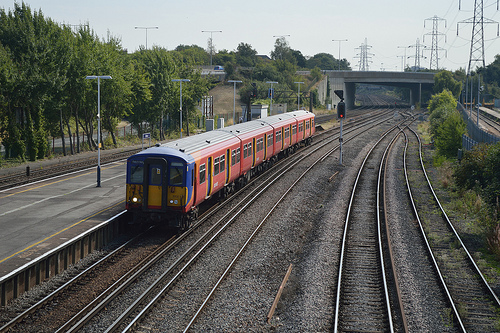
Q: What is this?
A: Train.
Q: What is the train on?
A: Train tracks.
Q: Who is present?
A: No one.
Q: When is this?
A: Daytime.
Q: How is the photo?
A: Clear.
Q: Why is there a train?
A: Travelling.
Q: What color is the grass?
A: Green.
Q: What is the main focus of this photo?
A: A train.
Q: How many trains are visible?
A: One.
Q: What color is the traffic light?
A: Red.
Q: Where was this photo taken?
A: On a train track.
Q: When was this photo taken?
A: Outside, during the daytime.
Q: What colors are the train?
A: Blue, yellow, and red.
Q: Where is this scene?
A: At the train tracks.